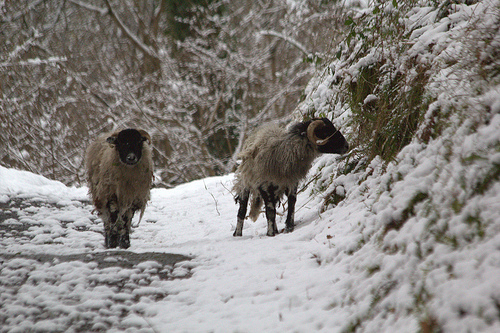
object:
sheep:
[232, 117, 350, 238]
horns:
[306, 120, 342, 146]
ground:
[1, 164, 320, 331]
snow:
[1, 167, 406, 332]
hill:
[292, 8, 499, 332]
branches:
[103, 0, 162, 60]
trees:
[154, 2, 223, 186]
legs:
[258, 185, 280, 237]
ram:
[285, 183, 297, 227]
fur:
[248, 147, 288, 179]